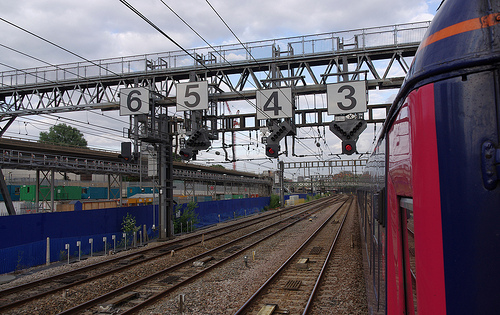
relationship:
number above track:
[119, 90, 152, 118] [6, 184, 362, 312]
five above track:
[181, 83, 201, 109] [6, 184, 362, 312]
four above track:
[261, 92, 284, 117] [6, 184, 362, 312]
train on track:
[346, 0, 493, 315] [6, 184, 362, 312]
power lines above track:
[11, 21, 382, 170] [6, 184, 362, 312]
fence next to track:
[7, 189, 272, 263] [6, 184, 362, 312]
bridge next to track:
[12, 132, 288, 188] [6, 184, 362, 312]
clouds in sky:
[37, 8, 206, 92] [5, 6, 451, 147]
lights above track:
[180, 143, 359, 158] [6, 184, 362, 312]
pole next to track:
[62, 241, 75, 263] [6, 184, 362, 312]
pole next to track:
[74, 239, 86, 265] [6, 184, 362, 312]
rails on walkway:
[10, 28, 377, 78] [0, 17, 435, 102]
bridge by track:
[12, 132, 288, 188] [6, 184, 362, 312]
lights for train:
[180, 143, 359, 158] [346, 0, 493, 315]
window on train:
[359, 192, 373, 250] [346, 0, 493, 315]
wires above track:
[6, 15, 358, 166] [6, 184, 362, 312]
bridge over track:
[12, 132, 288, 188] [6, 184, 362, 312]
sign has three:
[323, 76, 379, 126] [339, 85, 358, 109]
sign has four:
[251, 86, 294, 121] [261, 92, 284, 117]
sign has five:
[172, 80, 212, 116] [187, 83, 201, 106]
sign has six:
[118, 87, 153, 116] [127, 89, 142, 112]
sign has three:
[323, 76, 379, 126] [333, 85, 358, 111]